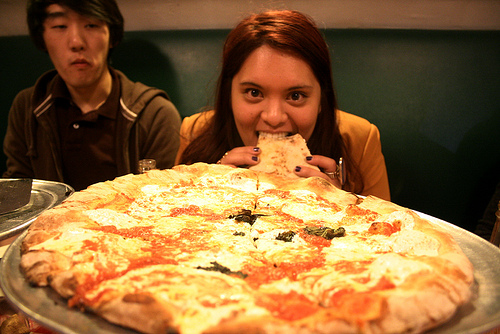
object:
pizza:
[16, 130, 477, 334]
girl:
[173, 7, 393, 204]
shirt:
[172, 104, 395, 205]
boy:
[1, 0, 183, 191]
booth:
[0, 0, 499, 334]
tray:
[0, 176, 77, 242]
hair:
[21, 0, 127, 61]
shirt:
[0, 67, 186, 192]